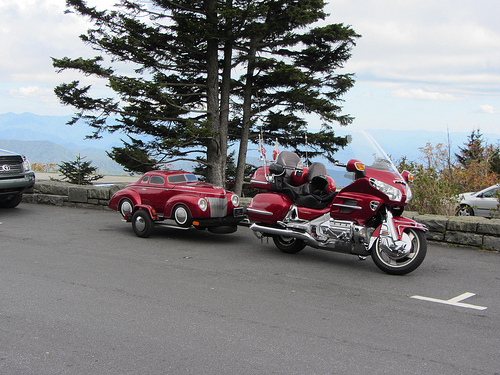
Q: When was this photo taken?
A: During the daytime.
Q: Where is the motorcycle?
A: In a parking spot.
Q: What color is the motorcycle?
A: Red.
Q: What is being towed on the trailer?
A: A little car.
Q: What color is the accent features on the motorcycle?
A: Chrome.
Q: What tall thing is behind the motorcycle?
A: A tree.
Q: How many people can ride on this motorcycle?
A: Two.